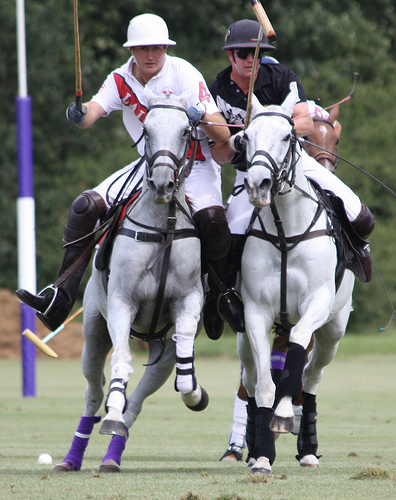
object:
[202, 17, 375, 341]
polo player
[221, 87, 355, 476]
horse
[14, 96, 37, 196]
indentifying color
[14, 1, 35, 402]
pole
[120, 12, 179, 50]
hat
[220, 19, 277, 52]
hat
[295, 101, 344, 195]
horse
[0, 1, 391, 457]
background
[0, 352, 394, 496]
area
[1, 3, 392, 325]
trees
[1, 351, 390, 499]
ground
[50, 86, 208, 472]
horse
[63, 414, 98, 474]
blue wrap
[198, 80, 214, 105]
number 4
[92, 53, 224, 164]
jersey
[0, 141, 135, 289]
crop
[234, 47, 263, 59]
sunglasses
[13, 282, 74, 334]
boot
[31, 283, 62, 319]
stirrup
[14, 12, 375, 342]
two people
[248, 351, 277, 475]
hooves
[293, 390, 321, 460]
sock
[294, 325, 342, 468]
horses leg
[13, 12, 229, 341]
man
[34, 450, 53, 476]
ball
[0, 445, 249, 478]
shade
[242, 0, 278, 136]
wood